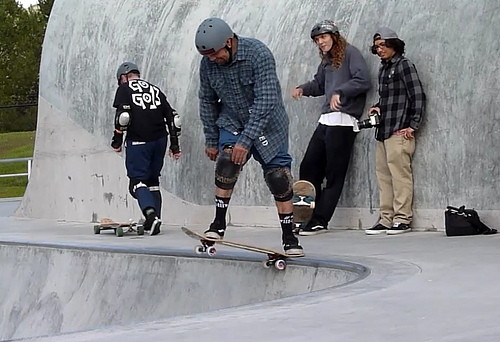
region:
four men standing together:
[56, 27, 439, 267]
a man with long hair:
[321, 18, 356, 77]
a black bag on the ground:
[443, 189, 490, 248]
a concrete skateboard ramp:
[2, 244, 333, 340]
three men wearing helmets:
[88, 5, 355, 128]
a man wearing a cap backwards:
[370, 21, 410, 65]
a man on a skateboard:
[193, 15, 293, 270]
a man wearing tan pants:
[370, 117, 422, 242]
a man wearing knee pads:
[208, 152, 299, 206]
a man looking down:
[187, 19, 241, 151]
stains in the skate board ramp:
[86, 256, 168, 298]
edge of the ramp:
[75, 236, 138, 261]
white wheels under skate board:
[190, 239, 227, 256]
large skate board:
[176, 221, 306, 276]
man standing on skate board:
[174, 23, 304, 241]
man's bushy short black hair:
[355, 28, 414, 53]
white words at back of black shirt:
[120, 75, 175, 117]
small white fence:
[3, 153, 19, 182]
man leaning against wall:
[286, 18, 365, 170]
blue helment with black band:
[178, 19, 239, 63]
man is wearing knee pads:
[200, 136, 308, 209]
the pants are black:
[290, 113, 371, 255]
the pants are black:
[257, 97, 353, 245]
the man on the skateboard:
[176, 16, 315, 258]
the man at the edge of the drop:
[175, 18, 335, 265]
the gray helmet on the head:
[168, 19, 248, 61]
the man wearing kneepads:
[198, 130, 241, 197]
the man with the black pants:
[290, 112, 355, 233]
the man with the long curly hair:
[332, 22, 353, 74]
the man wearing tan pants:
[377, 123, 427, 223]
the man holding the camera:
[350, 103, 393, 129]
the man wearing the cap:
[366, 23, 403, 45]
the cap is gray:
[366, 25, 403, 42]